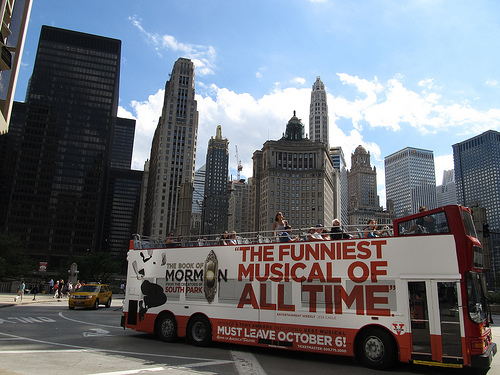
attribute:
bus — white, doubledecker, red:
[117, 197, 494, 374]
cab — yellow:
[66, 275, 115, 316]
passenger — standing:
[272, 210, 290, 236]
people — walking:
[17, 275, 72, 302]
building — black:
[35, 20, 124, 303]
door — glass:
[408, 280, 433, 355]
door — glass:
[433, 278, 472, 364]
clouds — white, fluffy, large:
[129, 62, 483, 163]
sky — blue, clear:
[26, 2, 497, 160]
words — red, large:
[230, 239, 400, 319]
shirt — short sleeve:
[275, 221, 289, 232]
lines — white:
[56, 309, 123, 333]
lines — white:
[4, 331, 237, 367]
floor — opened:
[132, 225, 461, 247]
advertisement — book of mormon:
[141, 242, 399, 319]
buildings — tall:
[30, 21, 498, 220]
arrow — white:
[81, 325, 114, 340]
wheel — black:
[151, 311, 180, 343]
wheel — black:
[184, 309, 216, 350]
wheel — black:
[348, 317, 405, 369]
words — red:
[162, 284, 208, 295]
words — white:
[215, 323, 351, 356]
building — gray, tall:
[151, 49, 213, 244]